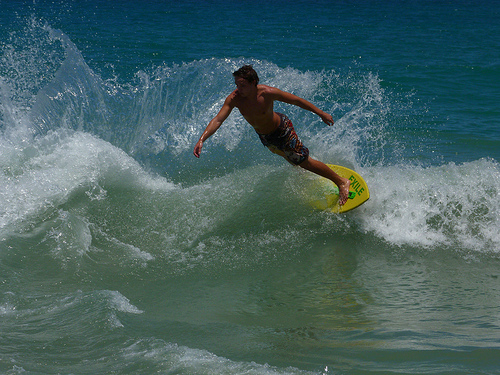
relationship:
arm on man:
[261, 82, 344, 145] [194, 66, 351, 205]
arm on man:
[175, 84, 231, 173] [194, 66, 351, 205]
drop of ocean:
[357, 52, 362, 62] [1, 0, 498, 372]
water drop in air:
[151, 50, 163, 57] [2, 3, 492, 120]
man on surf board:
[194, 66, 351, 205] [302, 164, 369, 213]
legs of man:
[283, 144, 354, 200] [186, 55, 352, 195]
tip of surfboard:
[354, 175, 369, 207] [307, 163, 369, 215]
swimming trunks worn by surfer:
[259, 111, 308, 166] [179, 60, 348, 201]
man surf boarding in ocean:
[194, 66, 351, 205] [1, 0, 498, 372]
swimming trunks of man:
[250, 110, 307, 157] [194, 66, 351, 205]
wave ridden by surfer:
[0, 75, 499, 263] [190, 65, 368, 201]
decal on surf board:
[346, 173, 364, 196] [278, 161, 369, 213]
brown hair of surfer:
[229, 65, 261, 85] [192, 63, 354, 208]